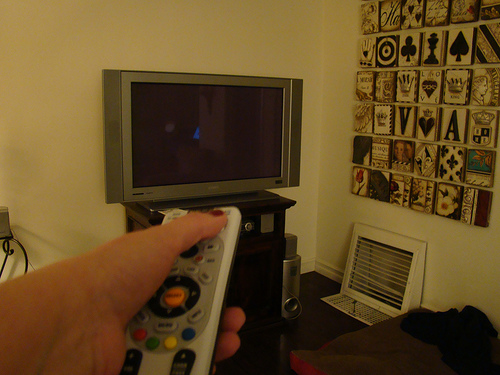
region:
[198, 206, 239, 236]
thumb on the button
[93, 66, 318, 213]
television that is on a stand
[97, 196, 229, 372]
black and silver remote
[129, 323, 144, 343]
small red button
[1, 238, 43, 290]
black wires running down the wall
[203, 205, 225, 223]
paint on the nail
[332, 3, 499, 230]
artwork on the wall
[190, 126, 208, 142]
glare on the screen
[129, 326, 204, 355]
row of four buttons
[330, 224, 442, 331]
vent leaning on the wall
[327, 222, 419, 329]
large white metal vent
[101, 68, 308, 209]
a grey flat screen tv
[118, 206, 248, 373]
a light grey and black remote control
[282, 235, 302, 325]
left side of a set of grey speakers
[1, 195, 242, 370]
hand holding a remote controller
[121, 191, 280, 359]
a dark colored tv stand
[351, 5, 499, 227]
decorative tiles on the wall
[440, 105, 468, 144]
tile with letter "A" on it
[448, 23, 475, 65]
tile with a spade on it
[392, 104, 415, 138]
tile with the letter "V" on it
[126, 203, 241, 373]
remote in a person's hand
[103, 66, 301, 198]
television is turned off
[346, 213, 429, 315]
vent on the bottom of the wall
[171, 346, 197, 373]
channel button on the remote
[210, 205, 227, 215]
red nail polish on the person's thumb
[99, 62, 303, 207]
flat screen television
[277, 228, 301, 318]
gray video game console on the ground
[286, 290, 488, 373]
cushion on the floor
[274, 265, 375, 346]
dark brown hardwood floor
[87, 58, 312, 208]
flat screen TV against a wall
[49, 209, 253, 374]
left hand holding remote control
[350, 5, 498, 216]
artwork with playing cards theme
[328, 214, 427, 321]
ventilation on wall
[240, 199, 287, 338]
part of a stand TV is on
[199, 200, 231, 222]
red nail polish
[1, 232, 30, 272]
iron scroll work displayed on non-visible furniture piece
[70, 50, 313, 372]
tv about to be powered on by remote control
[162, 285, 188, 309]
orange button on remote control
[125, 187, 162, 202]
brand name on television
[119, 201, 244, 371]
a white remote control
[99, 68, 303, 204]
a silver flat screen TV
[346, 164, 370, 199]
a framed piece of art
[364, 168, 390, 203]
a framed piece of art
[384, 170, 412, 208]
a framed piece of art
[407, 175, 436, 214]
a framed piece of art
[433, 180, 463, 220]
a framed piece of art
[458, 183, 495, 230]
a framed piece of art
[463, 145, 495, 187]
a framed piece of art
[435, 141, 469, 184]
a framed piece of art